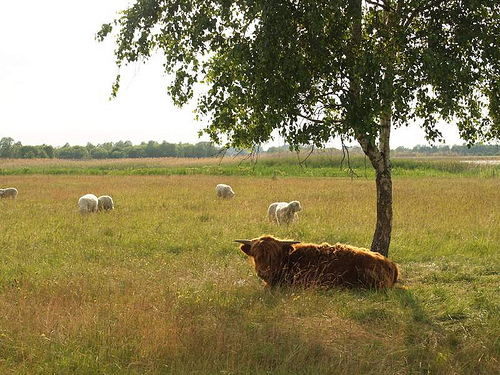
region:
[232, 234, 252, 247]
the horn of a bull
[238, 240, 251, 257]
the brown ear of a bull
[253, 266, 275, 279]
the nose of a bull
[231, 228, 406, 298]
a brown bull in the grass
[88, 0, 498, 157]
green leaves on a tree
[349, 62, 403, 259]
a brown and white tree trunk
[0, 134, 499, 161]
a row of green trees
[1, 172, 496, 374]
a field of green grass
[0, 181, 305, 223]
five sheep in a grassy field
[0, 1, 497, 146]
a gray sky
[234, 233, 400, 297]
A brown cow laying in grass under a tree.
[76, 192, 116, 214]
two white sheep standing in grass together.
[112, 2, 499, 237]
one lone tree giving shade to a brown cow.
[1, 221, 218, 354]
a field of green grass.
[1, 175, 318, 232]
five white sheep grazing in the grass.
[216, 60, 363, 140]
leaves on a variety of tree branches.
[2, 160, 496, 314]
a field of grass with different farm animals.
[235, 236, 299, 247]
two horns protruding from the brown cow's head.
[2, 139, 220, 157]
a row of green trees on the horizon.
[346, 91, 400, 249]
trunk of a tree behind the brown cow.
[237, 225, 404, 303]
the cow is lying down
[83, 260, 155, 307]
the grass is green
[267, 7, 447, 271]
the tree is tall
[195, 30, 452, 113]
the leaves are green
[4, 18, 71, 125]
the sky is white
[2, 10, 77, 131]
the sky is clear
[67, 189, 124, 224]
the sheep are white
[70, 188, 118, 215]
the sheep are standing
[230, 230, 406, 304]
the cow is brown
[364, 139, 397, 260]
the bark is brown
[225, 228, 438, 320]
Animal in the photo has brown fur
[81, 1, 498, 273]
One tree is in the foreground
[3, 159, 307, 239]
Five animals with white fur are in the background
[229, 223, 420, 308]
Animal has straight horns going side to side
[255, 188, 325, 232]
Animal is looking to its left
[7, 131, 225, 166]
Trees are in the background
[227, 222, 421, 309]
Animal has shaggy fur over eyes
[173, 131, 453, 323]
Animal is under the tree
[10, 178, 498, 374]
Tall grass is green and tan colored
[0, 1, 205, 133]
The sky is bright and white in color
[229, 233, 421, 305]
the animal has brown fur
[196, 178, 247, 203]
the animal has white fur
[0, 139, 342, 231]
there are five sheep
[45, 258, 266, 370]
the grass is tall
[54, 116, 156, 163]
trees in the background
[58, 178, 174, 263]
they are in a pasture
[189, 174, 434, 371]
the brown animal is larger than the white ones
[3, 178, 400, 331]
there are six animals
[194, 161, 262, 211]
a sheep is grazing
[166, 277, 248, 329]
there are yellow flowers